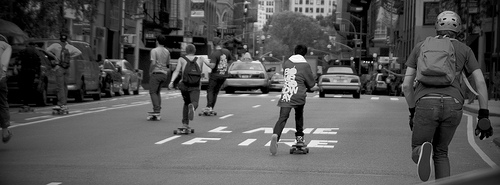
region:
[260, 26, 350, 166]
this is a person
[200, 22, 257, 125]
this is a person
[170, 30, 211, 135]
this is a person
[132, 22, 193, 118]
this is a person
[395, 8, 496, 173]
this is a person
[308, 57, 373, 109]
this is a car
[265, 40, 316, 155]
boy skateboarding down the fire lane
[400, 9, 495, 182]
guy skateboarding with a backpack on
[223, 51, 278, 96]
a taxi is driving down the road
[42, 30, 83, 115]
guy skateboarding in the bike lane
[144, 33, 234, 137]
three guys skateboarding down the road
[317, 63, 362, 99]
a car is driving down the road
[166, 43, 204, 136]
guy on a skateboard is wearing a backpack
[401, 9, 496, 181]
skateboarder is wearing gloves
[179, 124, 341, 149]
FIRE LANE is marked in the street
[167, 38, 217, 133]
girl riding a skateboard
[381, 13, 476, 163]
man wearing a backpack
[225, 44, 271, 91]
taxi cab in street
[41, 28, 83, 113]
man with his hands on his hips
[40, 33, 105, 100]
pick up truck parked on the side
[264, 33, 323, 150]
man jacket has writing on it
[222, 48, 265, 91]
the cab on the street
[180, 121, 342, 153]
the words on the street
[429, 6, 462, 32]
a helmet on the head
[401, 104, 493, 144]
the black gloves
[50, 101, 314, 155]
the skateboards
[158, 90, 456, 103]
the crosswalk lane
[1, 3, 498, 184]
the city view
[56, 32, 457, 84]
the backpacks on backs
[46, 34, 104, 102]
a van on the left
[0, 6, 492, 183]
the people in the street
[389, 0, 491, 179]
the person is running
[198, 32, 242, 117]
the person is running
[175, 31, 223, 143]
the person is running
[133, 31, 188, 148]
this is a person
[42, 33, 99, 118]
this is a person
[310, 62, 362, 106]
this is a car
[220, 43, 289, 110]
this is a car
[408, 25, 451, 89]
this is a back pack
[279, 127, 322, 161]
roller skates on rider's foot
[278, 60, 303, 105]
white symbol on back of jacket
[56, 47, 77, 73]
small black back pack